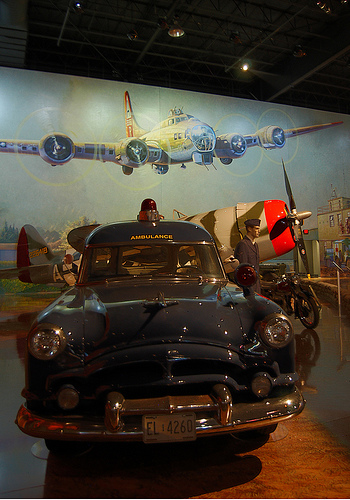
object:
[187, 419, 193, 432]
number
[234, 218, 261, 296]
man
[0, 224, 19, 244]
tree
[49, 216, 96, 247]
tree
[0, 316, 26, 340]
grass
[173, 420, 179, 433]
number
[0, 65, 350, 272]
plane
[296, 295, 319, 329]
wheel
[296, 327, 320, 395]
shadow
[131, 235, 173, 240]
text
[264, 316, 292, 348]
headlight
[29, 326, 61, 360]
headlight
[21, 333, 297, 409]
grill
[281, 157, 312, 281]
propellar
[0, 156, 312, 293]
airplane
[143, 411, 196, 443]
plate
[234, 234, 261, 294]
uniform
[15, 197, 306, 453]
ambulance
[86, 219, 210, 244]
roof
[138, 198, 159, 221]
light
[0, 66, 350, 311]
wall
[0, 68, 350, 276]
painting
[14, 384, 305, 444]
bumper